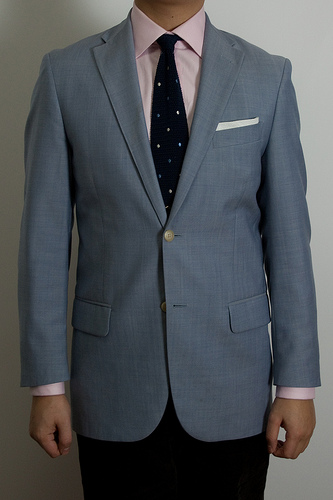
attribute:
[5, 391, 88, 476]
fist — closed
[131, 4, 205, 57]
collar — pink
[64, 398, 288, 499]
pants — black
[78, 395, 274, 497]
pants — black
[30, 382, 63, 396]
sleeve — pink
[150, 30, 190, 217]
tie — black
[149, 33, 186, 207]
tie — black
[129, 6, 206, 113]
shirt — pink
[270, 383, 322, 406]
cuff — pink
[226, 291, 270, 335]
flap — folded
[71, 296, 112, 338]
flap — folded